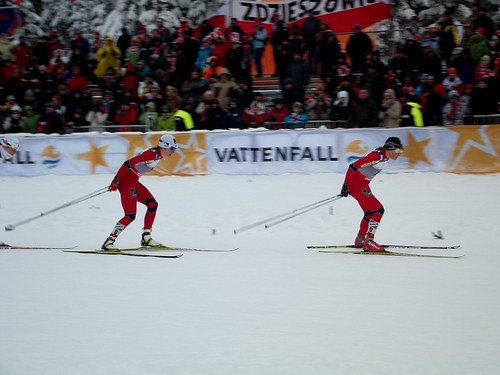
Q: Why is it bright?
A: Daytime.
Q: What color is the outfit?
A: Red.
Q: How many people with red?
A: Two.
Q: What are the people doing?
A: Skiing.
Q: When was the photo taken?
A: Daytime.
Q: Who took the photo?
A: A photographer.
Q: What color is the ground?
A: White.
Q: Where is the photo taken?
A: At a ski course.